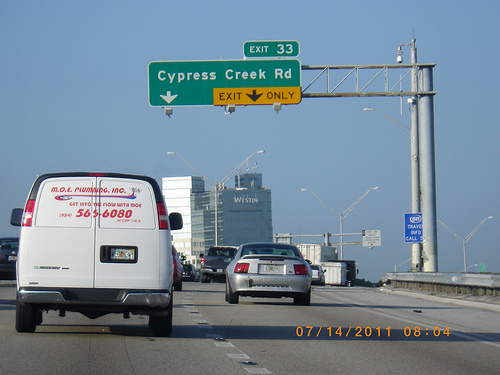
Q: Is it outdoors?
A: Yes, it is outdoors.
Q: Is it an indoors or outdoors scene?
A: It is outdoors.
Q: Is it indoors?
A: No, it is outdoors.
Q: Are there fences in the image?
A: No, there are no fences.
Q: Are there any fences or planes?
A: No, there are no fences or planes.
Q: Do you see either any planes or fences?
A: No, there are no fences or planes.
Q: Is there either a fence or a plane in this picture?
A: No, there are no fences or airplanes.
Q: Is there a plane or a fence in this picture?
A: No, there are no fences or airplanes.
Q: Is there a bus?
A: No, there are no buses.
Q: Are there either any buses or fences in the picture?
A: No, there are no buses or fences.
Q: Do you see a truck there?
A: Yes, there is a truck.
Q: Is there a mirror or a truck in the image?
A: Yes, there is a truck.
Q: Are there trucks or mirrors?
A: Yes, there is a truck.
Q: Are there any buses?
A: No, there are no buses.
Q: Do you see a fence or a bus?
A: No, there are no buses or fences.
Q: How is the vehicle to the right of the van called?
A: The vehicle is a truck.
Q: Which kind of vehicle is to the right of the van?
A: The vehicle is a truck.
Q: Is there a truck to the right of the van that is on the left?
A: Yes, there is a truck to the right of the van.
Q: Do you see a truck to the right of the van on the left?
A: Yes, there is a truck to the right of the van.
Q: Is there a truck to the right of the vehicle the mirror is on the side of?
A: Yes, there is a truck to the right of the van.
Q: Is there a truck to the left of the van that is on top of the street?
A: No, the truck is to the right of the van.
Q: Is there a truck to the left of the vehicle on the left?
A: No, the truck is to the right of the van.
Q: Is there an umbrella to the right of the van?
A: No, there is a truck to the right of the van.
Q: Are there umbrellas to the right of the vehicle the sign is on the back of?
A: No, there is a truck to the right of the van.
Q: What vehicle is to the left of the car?
A: The vehicle is a truck.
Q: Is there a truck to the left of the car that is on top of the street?
A: Yes, there is a truck to the left of the car.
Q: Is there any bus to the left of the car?
A: No, there is a truck to the left of the car.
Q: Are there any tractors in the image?
A: No, there are no tractors.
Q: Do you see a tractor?
A: No, there are no tractors.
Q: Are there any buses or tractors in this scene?
A: No, there are no tractors or buses.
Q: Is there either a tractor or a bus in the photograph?
A: No, there are no tractors or buses.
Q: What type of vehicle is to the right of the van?
A: The vehicle is a car.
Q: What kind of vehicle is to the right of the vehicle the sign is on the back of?
A: The vehicle is a car.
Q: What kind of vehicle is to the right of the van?
A: The vehicle is a car.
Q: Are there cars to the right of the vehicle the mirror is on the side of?
A: Yes, there is a car to the right of the van.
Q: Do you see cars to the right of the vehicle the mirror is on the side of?
A: Yes, there is a car to the right of the van.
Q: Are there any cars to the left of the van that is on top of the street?
A: No, the car is to the right of the van.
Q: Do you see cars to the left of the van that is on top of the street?
A: No, the car is to the right of the van.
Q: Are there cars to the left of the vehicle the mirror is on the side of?
A: No, the car is to the right of the van.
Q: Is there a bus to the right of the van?
A: No, there is a car to the right of the van.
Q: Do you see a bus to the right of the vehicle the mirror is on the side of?
A: No, there is a car to the right of the van.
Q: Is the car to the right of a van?
A: Yes, the car is to the right of a van.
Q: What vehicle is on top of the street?
A: The vehicle is a car.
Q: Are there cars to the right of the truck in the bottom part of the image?
A: No, the car is to the left of the truck.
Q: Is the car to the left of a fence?
A: No, the car is to the left of the truck.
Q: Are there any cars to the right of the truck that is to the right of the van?
A: Yes, there is a car to the right of the truck.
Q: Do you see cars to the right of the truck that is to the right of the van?
A: Yes, there is a car to the right of the truck.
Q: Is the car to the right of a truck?
A: Yes, the car is to the right of a truck.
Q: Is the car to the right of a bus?
A: No, the car is to the right of a truck.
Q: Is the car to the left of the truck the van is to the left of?
A: No, the car is to the right of the truck.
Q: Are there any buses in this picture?
A: No, there are no buses.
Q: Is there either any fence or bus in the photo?
A: No, there are no buses or fences.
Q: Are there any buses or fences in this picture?
A: No, there are no fences or buses.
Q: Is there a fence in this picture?
A: No, there are no fences.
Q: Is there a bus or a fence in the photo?
A: No, there are no fences or buses.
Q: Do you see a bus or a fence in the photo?
A: No, there are no fences or buses.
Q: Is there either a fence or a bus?
A: No, there are no fences or buses.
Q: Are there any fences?
A: No, there are no fences.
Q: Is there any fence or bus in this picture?
A: No, there are no fences or buses.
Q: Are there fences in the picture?
A: No, there are no fences.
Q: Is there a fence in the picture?
A: No, there are no fences.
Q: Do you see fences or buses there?
A: No, there are no fences or buses.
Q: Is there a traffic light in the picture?
A: No, there are no traffic lights.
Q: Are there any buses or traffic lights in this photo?
A: No, there are no traffic lights or buses.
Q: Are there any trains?
A: No, there are no trains.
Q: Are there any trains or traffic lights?
A: No, there are no trains or traffic lights.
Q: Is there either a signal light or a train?
A: No, there are no trains or traffic lights.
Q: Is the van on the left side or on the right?
A: The van is on the left of the image.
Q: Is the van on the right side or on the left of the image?
A: The van is on the left of the image.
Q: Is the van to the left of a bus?
A: No, the van is to the left of the truck.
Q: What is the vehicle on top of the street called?
A: The vehicle is a van.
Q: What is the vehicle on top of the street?
A: The vehicle is a van.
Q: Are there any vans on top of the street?
A: Yes, there is a van on top of the street.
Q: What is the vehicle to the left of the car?
A: The vehicle is a van.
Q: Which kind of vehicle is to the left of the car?
A: The vehicle is a van.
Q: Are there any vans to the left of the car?
A: Yes, there is a van to the left of the car.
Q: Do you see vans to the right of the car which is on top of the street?
A: No, the van is to the left of the car.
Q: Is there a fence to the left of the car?
A: No, there is a van to the left of the car.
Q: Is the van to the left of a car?
A: Yes, the van is to the left of a car.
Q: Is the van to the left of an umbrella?
A: No, the van is to the left of a car.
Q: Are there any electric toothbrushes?
A: No, there are no electric toothbrushes.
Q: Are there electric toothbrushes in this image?
A: No, there are no electric toothbrushes.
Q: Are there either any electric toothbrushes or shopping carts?
A: No, there are no electric toothbrushes or shopping carts.